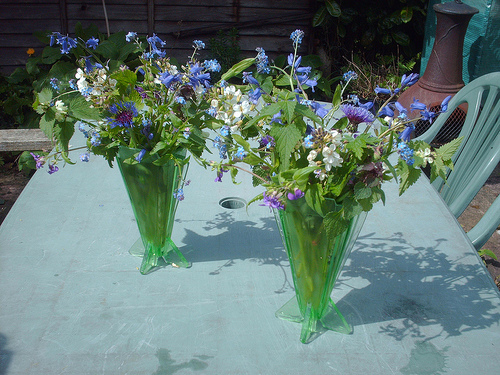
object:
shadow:
[177, 210, 297, 294]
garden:
[0, 2, 500, 145]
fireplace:
[392, 0, 471, 146]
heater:
[395, 1, 477, 150]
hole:
[219, 196, 248, 210]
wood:
[0, 128, 59, 152]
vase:
[274, 203, 368, 344]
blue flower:
[378, 101, 395, 119]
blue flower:
[441, 96, 452, 112]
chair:
[408, 70, 500, 249]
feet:
[275, 294, 351, 344]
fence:
[0, 0, 333, 99]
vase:
[115, 155, 192, 275]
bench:
[0, 99, 500, 374]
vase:
[276, 195, 370, 343]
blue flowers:
[32, 29, 460, 217]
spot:
[151, 349, 206, 375]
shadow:
[322, 238, 500, 348]